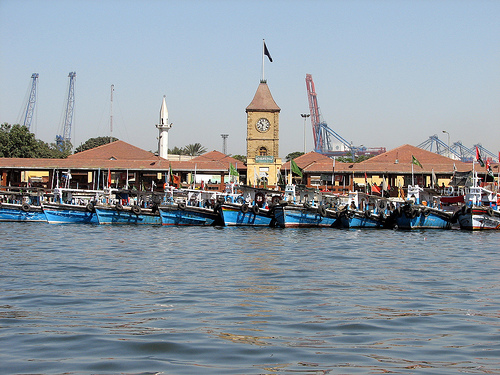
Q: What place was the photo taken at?
A: It was taken at the ocean.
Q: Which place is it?
A: It is an ocean.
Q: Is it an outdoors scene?
A: Yes, it is outdoors.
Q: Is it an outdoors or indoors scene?
A: It is outdoors.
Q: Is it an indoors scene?
A: No, it is outdoors.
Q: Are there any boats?
A: Yes, there is a boat.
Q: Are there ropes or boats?
A: Yes, there is a boat.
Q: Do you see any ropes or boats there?
A: Yes, there is a boat.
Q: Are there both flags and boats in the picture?
A: Yes, there are both a boat and a flag.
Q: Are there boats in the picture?
A: Yes, there is a boat.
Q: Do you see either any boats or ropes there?
A: Yes, there is a boat.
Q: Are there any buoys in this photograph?
A: No, there are no buoys.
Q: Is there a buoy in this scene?
A: No, there are no buoys.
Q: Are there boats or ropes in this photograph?
A: Yes, there is a boat.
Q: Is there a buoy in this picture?
A: No, there are no buoys.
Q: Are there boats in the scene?
A: Yes, there is a boat.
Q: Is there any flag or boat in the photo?
A: Yes, there is a boat.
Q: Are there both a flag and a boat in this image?
A: Yes, there are both a boat and a flag.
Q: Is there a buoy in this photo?
A: No, there are no buoys.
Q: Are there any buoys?
A: No, there are no buoys.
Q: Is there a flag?
A: Yes, there is a flag.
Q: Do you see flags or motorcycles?
A: Yes, there is a flag.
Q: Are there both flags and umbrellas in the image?
A: No, there is a flag but no umbrellas.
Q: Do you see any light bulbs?
A: No, there are no light bulbs.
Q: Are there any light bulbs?
A: No, there are no light bulbs.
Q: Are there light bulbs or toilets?
A: No, there are no light bulbs or toilets.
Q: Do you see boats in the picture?
A: Yes, there is a boat.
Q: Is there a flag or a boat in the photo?
A: Yes, there is a boat.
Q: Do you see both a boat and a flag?
A: Yes, there are both a boat and a flag.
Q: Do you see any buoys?
A: No, there are no buoys.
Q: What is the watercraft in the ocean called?
A: The watercraft is boats.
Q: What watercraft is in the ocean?
A: The watercraft is boats.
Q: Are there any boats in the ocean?
A: Yes, there are boats in the ocean.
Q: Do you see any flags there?
A: Yes, there is a flag.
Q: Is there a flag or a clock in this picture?
A: Yes, there is a flag.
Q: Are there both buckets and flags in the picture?
A: No, there is a flag but no buckets.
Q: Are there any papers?
A: No, there are no papers.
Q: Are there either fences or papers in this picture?
A: No, there are no papers or fences.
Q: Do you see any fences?
A: No, there are no fences.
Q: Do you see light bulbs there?
A: No, there are no light bulbs.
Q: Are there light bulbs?
A: No, there are no light bulbs.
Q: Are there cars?
A: No, there are no cars.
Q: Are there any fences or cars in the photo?
A: No, there are no cars or fences.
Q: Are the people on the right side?
A: Yes, the people are on the right of the image.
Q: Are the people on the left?
A: No, the people are on the right of the image.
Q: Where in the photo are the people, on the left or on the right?
A: The people are on the right of the image.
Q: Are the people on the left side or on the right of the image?
A: The people are on the right of the image.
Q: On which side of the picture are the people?
A: The people are on the right of the image.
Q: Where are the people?
A: The people are on the dock.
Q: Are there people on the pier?
A: Yes, there are people on the pier.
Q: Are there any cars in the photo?
A: No, there are no cars.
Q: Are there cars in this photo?
A: No, there are no cars.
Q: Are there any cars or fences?
A: No, there are no cars or fences.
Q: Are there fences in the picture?
A: No, there are no fences.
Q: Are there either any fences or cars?
A: No, there are no fences or cars.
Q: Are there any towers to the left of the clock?
A: Yes, there is a tower to the left of the clock.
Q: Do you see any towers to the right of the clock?
A: No, the tower is to the left of the clock.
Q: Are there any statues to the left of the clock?
A: No, there is a tower to the left of the clock.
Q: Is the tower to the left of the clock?
A: Yes, the tower is to the left of the clock.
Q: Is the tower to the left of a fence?
A: No, the tower is to the left of the clock.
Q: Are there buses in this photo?
A: No, there are no buses.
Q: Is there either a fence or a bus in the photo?
A: No, there are no buses or fences.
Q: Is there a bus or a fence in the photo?
A: No, there are no buses or fences.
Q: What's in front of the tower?
A: The building is in front of the tower.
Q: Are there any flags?
A: Yes, there is a flag.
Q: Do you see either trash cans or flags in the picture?
A: Yes, there is a flag.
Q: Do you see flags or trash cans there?
A: Yes, there is a flag.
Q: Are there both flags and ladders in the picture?
A: No, there is a flag but no ladders.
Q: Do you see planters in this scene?
A: No, there are no planters.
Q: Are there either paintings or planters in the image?
A: No, there are no planters or paintings.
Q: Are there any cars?
A: No, there are no cars.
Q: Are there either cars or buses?
A: No, there are no cars or buses.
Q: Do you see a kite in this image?
A: No, there are no kites.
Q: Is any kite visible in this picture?
A: No, there are no kites.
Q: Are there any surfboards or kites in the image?
A: No, there are no kites or surfboards.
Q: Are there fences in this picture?
A: No, there are no fences.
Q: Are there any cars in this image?
A: No, there are no cars.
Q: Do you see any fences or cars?
A: No, there are no cars or fences.